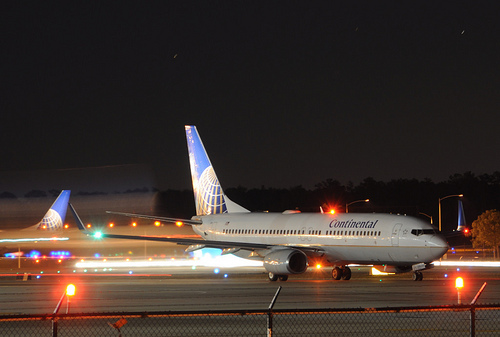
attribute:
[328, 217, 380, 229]
continental — blue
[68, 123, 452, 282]
plane — large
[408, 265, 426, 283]
landing gear — down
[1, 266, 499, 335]
runway — asphalt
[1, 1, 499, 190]
sky — dark, black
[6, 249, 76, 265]
lights — blue, red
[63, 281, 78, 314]
light — orange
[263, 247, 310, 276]
engine — large, white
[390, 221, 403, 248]
door — white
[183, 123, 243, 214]
tail — illuminated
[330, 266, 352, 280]
wheels — round, black